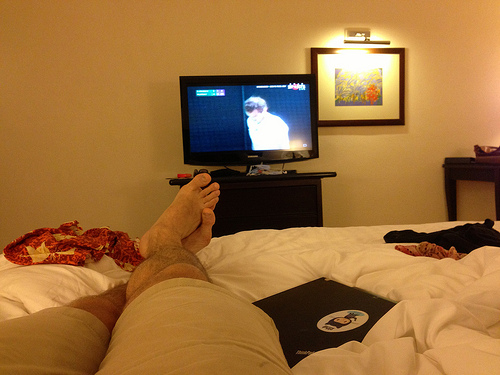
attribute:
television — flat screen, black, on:
[177, 74, 318, 165]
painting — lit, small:
[312, 47, 408, 126]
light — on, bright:
[343, 25, 391, 46]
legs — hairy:
[3, 173, 274, 373]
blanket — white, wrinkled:
[0, 221, 498, 372]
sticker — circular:
[316, 308, 369, 332]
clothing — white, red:
[0, 217, 139, 274]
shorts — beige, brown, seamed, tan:
[0, 286, 285, 371]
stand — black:
[173, 171, 337, 231]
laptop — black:
[249, 271, 402, 367]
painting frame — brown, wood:
[310, 47, 405, 124]